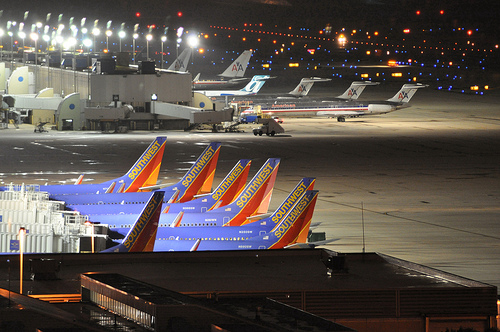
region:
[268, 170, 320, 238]
tails of the airplane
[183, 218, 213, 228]
windows on the airplane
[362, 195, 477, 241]
the roadway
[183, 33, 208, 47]
a light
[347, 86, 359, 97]
logo on the tail of the plane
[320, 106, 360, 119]
wing of the airplane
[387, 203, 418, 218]
the yellow line on the roadway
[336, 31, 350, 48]
the light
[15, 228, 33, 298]
a white pole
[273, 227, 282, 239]
yellow letter on plane tail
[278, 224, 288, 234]
yellow letter on plane tail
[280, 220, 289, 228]
yellow letter on plane tail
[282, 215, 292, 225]
yellow letter on plane tail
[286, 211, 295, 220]
yellow letter on plane tail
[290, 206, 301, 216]
yellow letter on plane tail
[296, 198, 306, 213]
yellow letter on plane tail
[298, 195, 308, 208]
yellow letter on plane tail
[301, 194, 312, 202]
yellow letter on plane tail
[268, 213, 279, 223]
yellow letter on plane tail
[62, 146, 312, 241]
five planes lined up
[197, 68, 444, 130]
planes at the gate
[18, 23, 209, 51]
lights for the planes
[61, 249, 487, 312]
roof of a building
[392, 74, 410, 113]
tail of the plane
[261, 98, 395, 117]
plane is silver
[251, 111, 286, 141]
cargo truck by the plane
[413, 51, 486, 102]
lights on the runway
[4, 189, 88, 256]
gates for passengers to board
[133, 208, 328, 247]
airplane on the runway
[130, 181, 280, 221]
airplane on the runway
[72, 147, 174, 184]
airplane on the runway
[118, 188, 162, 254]
airplane on the runway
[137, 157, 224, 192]
airplane on the runway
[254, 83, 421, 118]
airplane on the runway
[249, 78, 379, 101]
airplane on the runway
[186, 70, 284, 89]
airplane on the runway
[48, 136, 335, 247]
six Southwest airlines in a row at the airport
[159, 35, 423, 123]
six American Airlines airliners at the airport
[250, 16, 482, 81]
multitude of colored lights at the airport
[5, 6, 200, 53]
many bright lights illuminating the tarmac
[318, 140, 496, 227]
grey cement paved tarmac at the airport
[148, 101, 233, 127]
white jetbridge leading to an aircraft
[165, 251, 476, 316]
the roof of a terminal building at the airport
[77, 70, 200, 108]
the end of a terminal building at the airport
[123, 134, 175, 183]
yellow, red and orange tail of the airliner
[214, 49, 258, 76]
tail of the airliner with AA on it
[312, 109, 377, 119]
plane has a wing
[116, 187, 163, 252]
plane has a wing